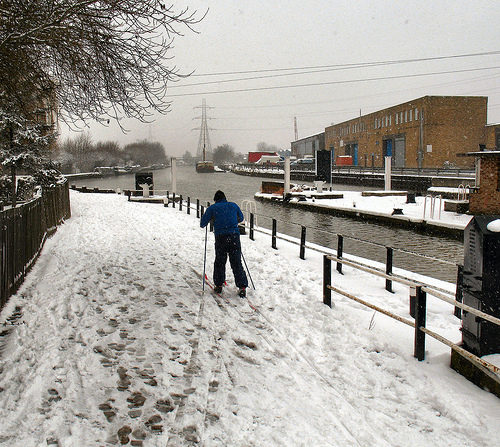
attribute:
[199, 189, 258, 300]
skier — skiing, walking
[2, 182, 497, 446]
sidewalk — snow covered, white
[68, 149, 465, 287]
canal — calm, dark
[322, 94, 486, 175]
building — brick, brown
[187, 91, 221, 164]
tower — in the distance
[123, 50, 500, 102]
power wires — overhead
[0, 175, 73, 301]
fence — wooden, black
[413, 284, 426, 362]
post — black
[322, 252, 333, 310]
post — black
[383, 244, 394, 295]
post — black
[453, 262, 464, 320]
post — black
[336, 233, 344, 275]
post — black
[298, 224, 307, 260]
post — black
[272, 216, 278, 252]
post — black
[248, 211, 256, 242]
post — black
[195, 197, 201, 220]
post — black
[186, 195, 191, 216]
post — black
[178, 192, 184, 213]
post — black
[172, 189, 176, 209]
post — black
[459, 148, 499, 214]
building — brick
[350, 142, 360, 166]
door — blue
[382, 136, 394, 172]
door — blue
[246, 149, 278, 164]
truck — red